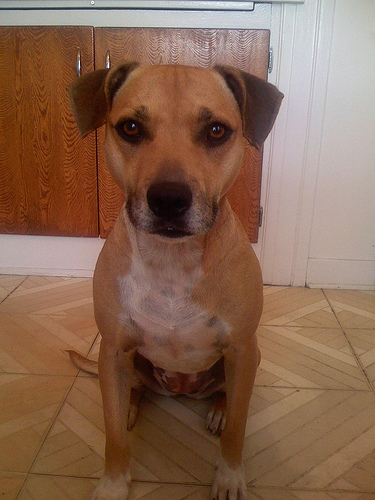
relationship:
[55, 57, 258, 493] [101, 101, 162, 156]
dog has eye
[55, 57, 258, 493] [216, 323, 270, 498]
dog has leg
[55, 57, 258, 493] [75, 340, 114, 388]
dog has tail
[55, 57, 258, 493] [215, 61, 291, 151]
dog has ear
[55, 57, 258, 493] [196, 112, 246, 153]
dog has eye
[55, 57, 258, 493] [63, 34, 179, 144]
dog has ear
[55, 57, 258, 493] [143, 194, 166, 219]
dog has nostril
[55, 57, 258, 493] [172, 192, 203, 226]
dog has nostril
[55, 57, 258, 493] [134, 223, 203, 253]
dog has mouth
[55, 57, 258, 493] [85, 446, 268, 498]
dog has paws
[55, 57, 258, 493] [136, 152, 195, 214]
dog has nose